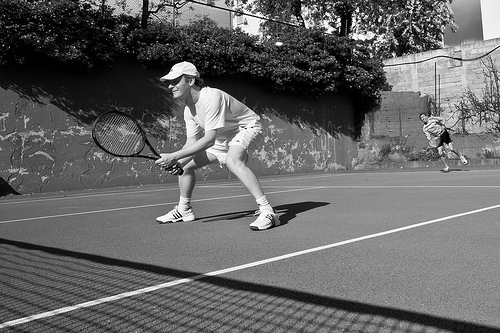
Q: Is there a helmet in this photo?
A: No, there are no helmets.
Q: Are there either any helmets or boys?
A: No, there are no helmets or boys.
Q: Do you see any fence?
A: No, there are no fences.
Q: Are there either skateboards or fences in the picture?
A: No, there are no fences or skateboards.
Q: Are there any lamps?
A: No, there are no lamps.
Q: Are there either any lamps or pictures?
A: No, there are no lamps or pictures.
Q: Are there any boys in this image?
A: No, there are no boys.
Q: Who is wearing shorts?
A: The man is wearing shorts.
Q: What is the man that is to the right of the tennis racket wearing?
A: The man is wearing shorts.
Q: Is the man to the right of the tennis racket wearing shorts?
A: Yes, the man is wearing shorts.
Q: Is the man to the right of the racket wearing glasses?
A: No, the man is wearing shorts.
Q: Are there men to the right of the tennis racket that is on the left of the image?
A: Yes, there is a man to the right of the tennis racket.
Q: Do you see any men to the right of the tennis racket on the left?
A: Yes, there is a man to the right of the tennis racket.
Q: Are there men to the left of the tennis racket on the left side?
A: No, the man is to the right of the racket.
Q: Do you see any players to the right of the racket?
A: No, there is a man to the right of the racket.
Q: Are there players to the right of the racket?
A: No, there is a man to the right of the racket.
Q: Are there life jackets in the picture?
A: No, there are no life jackets.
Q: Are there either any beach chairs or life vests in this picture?
A: No, there are no life vests or beach chairs.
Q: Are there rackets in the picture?
A: Yes, there is a racket.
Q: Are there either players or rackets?
A: Yes, there is a racket.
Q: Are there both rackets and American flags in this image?
A: No, there is a racket but no American flags.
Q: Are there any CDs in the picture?
A: No, there are no cds.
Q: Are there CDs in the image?
A: No, there are no cds.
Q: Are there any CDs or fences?
A: No, there are no CDs or fences.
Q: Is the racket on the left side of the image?
A: Yes, the racket is on the left of the image.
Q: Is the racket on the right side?
A: No, the racket is on the left of the image.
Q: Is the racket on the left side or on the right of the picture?
A: The racket is on the left of the image.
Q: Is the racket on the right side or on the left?
A: The racket is on the left of the image.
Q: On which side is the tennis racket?
A: The tennis racket is on the left of the image.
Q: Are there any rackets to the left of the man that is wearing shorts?
A: Yes, there is a racket to the left of the man.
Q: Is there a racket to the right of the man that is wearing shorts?
A: No, the racket is to the left of the man.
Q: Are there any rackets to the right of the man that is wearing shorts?
A: No, the racket is to the left of the man.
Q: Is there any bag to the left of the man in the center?
A: No, there is a racket to the left of the man.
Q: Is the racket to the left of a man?
A: Yes, the racket is to the left of a man.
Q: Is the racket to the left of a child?
A: No, the racket is to the left of a man.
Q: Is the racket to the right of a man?
A: No, the racket is to the left of a man.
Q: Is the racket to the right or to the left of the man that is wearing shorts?
A: The racket is to the left of the man.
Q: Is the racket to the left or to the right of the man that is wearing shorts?
A: The racket is to the left of the man.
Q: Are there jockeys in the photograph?
A: No, there are no jockeys.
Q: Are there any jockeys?
A: No, there are no jockeys.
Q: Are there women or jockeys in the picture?
A: No, there are no jockeys or women.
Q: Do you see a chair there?
A: No, there are no chairs.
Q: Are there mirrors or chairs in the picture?
A: No, there are no chairs or mirrors.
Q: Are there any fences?
A: No, there are no fences.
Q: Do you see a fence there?
A: No, there are no fences.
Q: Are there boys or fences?
A: No, there are no fences or boys.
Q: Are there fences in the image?
A: No, there are no fences.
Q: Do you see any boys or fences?
A: No, there are no fences or boys.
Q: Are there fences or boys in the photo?
A: No, there are no fences or boys.